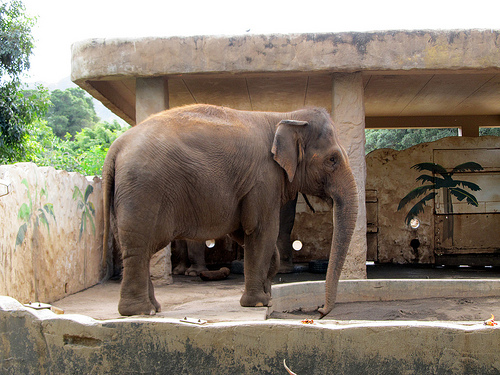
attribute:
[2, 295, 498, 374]
wall — stone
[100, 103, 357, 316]
elephant — large, gray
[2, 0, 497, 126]
sky — white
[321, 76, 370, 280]
post — stone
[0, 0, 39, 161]
tree — tall, green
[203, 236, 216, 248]
hole — round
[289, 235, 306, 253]
hole — round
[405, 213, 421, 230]
hole — round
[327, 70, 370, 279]
column — sandy colored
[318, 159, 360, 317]
trunk — long, gray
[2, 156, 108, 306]
wall — stone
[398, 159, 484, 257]
tree — painted